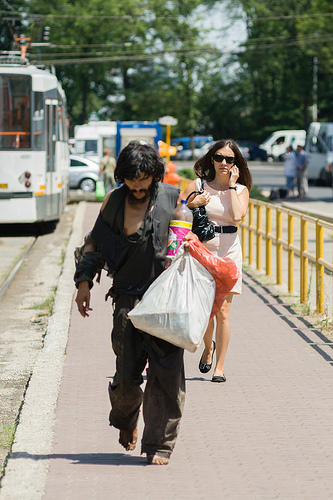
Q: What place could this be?
A: It is a sidewalk.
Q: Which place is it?
A: It is a sidewalk.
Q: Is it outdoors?
A: Yes, it is outdoors.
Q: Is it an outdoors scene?
A: Yes, it is outdoors.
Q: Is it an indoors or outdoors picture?
A: It is outdoors.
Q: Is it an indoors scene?
A: No, it is outdoors.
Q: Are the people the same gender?
A: No, they are both male and female.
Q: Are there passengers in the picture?
A: No, there are no passengers.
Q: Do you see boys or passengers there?
A: No, there are no passengers or boys.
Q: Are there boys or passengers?
A: No, there are no passengers or boys.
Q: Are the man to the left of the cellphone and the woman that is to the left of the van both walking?
A: Yes, both the man and the woman are walking.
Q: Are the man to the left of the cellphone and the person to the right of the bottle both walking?
A: Yes, both the man and the woman are walking.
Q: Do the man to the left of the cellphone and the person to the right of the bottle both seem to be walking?
A: Yes, both the man and the woman are walking.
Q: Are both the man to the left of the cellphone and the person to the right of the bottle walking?
A: Yes, both the man and the woman are walking.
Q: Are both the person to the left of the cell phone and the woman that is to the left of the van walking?
A: Yes, both the man and the woman are walking.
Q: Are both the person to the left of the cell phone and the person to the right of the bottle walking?
A: Yes, both the man and the woman are walking.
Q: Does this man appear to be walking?
A: Yes, the man is walking.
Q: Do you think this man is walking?
A: Yes, the man is walking.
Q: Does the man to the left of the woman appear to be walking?
A: Yes, the man is walking.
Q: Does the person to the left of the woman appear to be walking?
A: Yes, the man is walking.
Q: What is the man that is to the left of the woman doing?
A: The man is walking.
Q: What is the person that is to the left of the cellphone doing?
A: The man is walking.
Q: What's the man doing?
A: The man is walking.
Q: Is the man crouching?
A: No, the man is walking.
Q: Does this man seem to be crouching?
A: No, the man is walking.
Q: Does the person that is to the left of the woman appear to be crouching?
A: No, the man is walking.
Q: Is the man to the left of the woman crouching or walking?
A: The man is walking.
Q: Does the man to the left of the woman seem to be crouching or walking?
A: The man is walking.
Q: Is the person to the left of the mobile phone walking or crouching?
A: The man is walking.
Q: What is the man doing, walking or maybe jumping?
A: The man is walking.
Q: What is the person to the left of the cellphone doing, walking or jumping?
A: The man is walking.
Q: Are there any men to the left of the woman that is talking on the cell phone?
A: Yes, there is a man to the left of the woman.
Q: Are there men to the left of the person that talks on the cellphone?
A: Yes, there is a man to the left of the woman.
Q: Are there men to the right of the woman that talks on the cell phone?
A: No, the man is to the left of the woman.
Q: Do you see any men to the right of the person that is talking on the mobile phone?
A: No, the man is to the left of the woman.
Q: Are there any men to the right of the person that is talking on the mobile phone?
A: No, the man is to the left of the woman.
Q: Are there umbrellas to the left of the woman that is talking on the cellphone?
A: No, there is a man to the left of the woman.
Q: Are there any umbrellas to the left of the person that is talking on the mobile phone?
A: No, there is a man to the left of the woman.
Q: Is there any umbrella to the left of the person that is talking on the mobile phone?
A: No, there is a man to the left of the woman.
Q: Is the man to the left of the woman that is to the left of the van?
A: Yes, the man is to the left of the woman.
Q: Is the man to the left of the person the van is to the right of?
A: Yes, the man is to the left of the woman.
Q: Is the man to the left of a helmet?
A: No, the man is to the left of the woman.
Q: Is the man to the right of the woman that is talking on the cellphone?
A: No, the man is to the left of the woman.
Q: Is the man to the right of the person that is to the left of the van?
A: No, the man is to the left of the woman.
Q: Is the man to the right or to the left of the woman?
A: The man is to the left of the woman.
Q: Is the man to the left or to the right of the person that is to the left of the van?
A: The man is to the left of the woman.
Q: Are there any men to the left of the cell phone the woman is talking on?
A: Yes, there is a man to the left of the cellphone.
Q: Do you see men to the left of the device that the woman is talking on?
A: Yes, there is a man to the left of the cellphone.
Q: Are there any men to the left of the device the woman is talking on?
A: Yes, there is a man to the left of the cellphone.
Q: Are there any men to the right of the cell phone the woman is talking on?
A: No, the man is to the left of the mobile phone.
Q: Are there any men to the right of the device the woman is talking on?
A: No, the man is to the left of the mobile phone.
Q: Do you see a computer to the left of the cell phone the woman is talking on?
A: No, there is a man to the left of the cellphone.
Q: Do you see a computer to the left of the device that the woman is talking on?
A: No, there is a man to the left of the cellphone.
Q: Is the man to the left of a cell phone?
A: Yes, the man is to the left of a cell phone.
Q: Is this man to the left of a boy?
A: No, the man is to the left of a cell phone.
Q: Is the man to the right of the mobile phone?
A: No, the man is to the left of the mobile phone.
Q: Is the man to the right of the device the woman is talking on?
A: No, the man is to the left of the mobile phone.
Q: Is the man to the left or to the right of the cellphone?
A: The man is to the left of the cellphone.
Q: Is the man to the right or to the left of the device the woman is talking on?
A: The man is to the left of the cellphone.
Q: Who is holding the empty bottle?
A: The man is holding the bottle.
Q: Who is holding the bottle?
A: The man is holding the bottle.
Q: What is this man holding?
A: The man is holding the bottle.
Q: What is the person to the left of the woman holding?
A: The man is holding the bottle.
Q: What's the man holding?
A: The man is holding the bottle.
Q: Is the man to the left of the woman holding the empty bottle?
A: Yes, the man is holding the bottle.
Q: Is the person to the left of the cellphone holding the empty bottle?
A: Yes, the man is holding the bottle.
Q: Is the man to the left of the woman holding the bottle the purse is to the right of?
A: Yes, the man is holding the bottle.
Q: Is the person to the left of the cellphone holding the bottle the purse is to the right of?
A: Yes, the man is holding the bottle.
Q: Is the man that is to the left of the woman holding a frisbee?
A: No, the man is holding the bottle.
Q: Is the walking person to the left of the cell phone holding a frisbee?
A: No, the man is holding the bottle.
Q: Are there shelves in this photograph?
A: No, there are no shelves.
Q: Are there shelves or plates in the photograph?
A: No, there are no shelves or plates.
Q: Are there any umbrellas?
A: No, there are no umbrellas.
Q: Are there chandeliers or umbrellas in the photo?
A: No, there are no umbrellas or chandeliers.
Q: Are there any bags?
A: Yes, there is a bag.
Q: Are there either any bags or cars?
A: Yes, there is a bag.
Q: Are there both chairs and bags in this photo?
A: No, there is a bag but no chairs.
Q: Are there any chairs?
A: No, there are no chairs.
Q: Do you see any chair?
A: No, there are no chairs.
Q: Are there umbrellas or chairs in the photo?
A: No, there are no chairs or umbrellas.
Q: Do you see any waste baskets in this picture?
A: No, there are no waste baskets.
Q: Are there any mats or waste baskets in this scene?
A: No, there are no waste baskets or mats.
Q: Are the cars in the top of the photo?
A: Yes, the cars are in the top of the image.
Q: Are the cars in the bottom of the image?
A: No, the cars are in the top of the image.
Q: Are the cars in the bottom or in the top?
A: The cars are in the top of the image.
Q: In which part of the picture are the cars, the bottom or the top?
A: The cars are in the top of the image.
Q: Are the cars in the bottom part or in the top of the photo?
A: The cars are in the top of the image.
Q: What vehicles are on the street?
A: The vehicles are cars.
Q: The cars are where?
A: The cars are on the street.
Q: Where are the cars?
A: The cars are on the street.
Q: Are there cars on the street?
A: Yes, there are cars on the street.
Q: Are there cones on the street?
A: No, there are cars on the street.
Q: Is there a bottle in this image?
A: Yes, there is a bottle.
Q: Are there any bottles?
A: Yes, there is a bottle.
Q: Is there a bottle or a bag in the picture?
A: Yes, there is a bottle.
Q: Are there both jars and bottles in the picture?
A: No, there is a bottle but no jars.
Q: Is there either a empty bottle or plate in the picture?
A: Yes, there is an empty bottle.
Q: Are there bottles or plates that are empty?
A: Yes, the bottle is empty.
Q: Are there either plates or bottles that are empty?
A: Yes, the bottle is empty.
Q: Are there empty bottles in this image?
A: Yes, there is an empty bottle.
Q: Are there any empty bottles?
A: Yes, there is an empty bottle.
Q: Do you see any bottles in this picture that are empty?
A: Yes, there is a bottle that is empty.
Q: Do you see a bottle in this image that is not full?
A: Yes, there is a empty bottle.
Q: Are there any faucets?
A: No, there are no faucets.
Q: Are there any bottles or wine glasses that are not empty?
A: No, there is a bottle but it is empty.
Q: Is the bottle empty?
A: Yes, the bottle is empty.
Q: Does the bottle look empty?
A: Yes, the bottle is empty.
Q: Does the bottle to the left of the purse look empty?
A: Yes, the bottle is empty.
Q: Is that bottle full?
A: No, the bottle is empty.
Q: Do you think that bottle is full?
A: No, the bottle is empty.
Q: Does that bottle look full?
A: No, the bottle is empty.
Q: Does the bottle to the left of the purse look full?
A: No, the bottle is empty.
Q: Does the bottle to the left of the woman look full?
A: No, the bottle is empty.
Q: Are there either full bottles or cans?
A: No, there is a bottle but it is empty.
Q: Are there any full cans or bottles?
A: No, there is a bottle but it is empty.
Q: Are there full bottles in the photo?
A: No, there is a bottle but it is empty.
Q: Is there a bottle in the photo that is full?
A: No, there is a bottle but it is empty.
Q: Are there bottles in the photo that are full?
A: No, there is a bottle but it is empty.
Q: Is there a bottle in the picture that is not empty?
A: No, there is a bottle but it is empty.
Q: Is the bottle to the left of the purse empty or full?
A: The bottle is empty.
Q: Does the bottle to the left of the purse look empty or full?
A: The bottle is empty.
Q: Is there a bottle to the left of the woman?
A: Yes, there is a bottle to the left of the woman.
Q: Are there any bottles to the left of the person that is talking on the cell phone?
A: Yes, there is a bottle to the left of the woman.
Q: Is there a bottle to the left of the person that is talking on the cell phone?
A: Yes, there is a bottle to the left of the woman.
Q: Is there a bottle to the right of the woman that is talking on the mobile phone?
A: No, the bottle is to the left of the woman.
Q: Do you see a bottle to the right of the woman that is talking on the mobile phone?
A: No, the bottle is to the left of the woman.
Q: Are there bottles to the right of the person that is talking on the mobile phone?
A: No, the bottle is to the left of the woman.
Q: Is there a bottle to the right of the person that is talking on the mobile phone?
A: No, the bottle is to the left of the woman.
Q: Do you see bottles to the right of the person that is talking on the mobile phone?
A: No, the bottle is to the left of the woman.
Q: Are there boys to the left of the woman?
A: No, there is a bottle to the left of the woman.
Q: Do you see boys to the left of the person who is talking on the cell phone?
A: No, there is a bottle to the left of the woman.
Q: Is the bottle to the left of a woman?
A: Yes, the bottle is to the left of a woman.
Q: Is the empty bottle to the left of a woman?
A: Yes, the bottle is to the left of a woman.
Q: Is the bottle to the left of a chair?
A: No, the bottle is to the left of a woman.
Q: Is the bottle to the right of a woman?
A: No, the bottle is to the left of a woman.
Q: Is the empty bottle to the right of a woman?
A: No, the bottle is to the left of a woman.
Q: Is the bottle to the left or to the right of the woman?
A: The bottle is to the left of the woman.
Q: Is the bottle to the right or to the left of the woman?
A: The bottle is to the left of the woman.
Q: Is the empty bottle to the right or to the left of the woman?
A: The bottle is to the left of the woman.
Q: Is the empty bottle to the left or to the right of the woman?
A: The bottle is to the left of the woman.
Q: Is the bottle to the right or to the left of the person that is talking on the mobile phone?
A: The bottle is to the left of the woman.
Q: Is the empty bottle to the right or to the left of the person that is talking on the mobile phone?
A: The bottle is to the left of the woman.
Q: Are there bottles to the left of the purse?
A: Yes, there is a bottle to the left of the purse.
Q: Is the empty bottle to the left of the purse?
A: Yes, the bottle is to the left of the purse.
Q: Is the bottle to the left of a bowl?
A: No, the bottle is to the left of the purse.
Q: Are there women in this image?
A: Yes, there is a woman.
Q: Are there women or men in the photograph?
A: Yes, there is a woman.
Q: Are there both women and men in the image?
A: Yes, there are both a woman and a man.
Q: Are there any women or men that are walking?
A: Yes, the woman is walking.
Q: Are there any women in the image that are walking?
A: Yes, there is a woman that is walking.